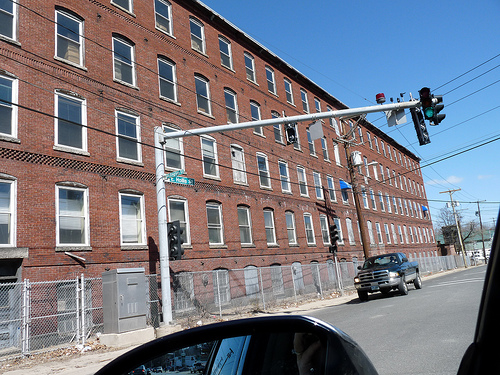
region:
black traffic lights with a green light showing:
[409, 87, 449, 145]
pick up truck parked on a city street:
[351, 252, 421, 299]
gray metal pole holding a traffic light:
[152, 124, 174, 334]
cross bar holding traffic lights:
[166, 98, 428, 145]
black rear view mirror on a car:
[98, 312, 380, 372]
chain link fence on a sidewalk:
[0, 252, 475, 362]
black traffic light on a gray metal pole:
[166, 220, 186, 265]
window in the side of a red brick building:
[0, 1, 432, 256]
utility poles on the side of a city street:
[439, 184, 492, 269]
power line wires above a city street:
[346, 53, 496, 188]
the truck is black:
[351, 239, 423, 289]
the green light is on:
[418, 105, 440, 125]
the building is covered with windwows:
[138, 90, 436, 250]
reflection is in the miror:
[173, 340, 321, 374]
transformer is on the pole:
[345, 148, 369, 173]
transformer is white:
[347, 151, 369, 164]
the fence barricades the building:
[245, 263, 341, 310]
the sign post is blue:
[161, 165, 198, 187]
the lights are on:
[343, 264, 402, 286]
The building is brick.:
[1, 0, 452, 367]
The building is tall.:
[0, 0, 455, 368]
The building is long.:
[1, 0, 447, 363]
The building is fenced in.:
[1, 0, 446, 372]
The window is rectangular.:
[51, 85, 94, 158]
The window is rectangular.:
[51, 178, 98, 257]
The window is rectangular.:
[49, 4, 86, 71]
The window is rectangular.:
[103, 27, 150, 99]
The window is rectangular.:
[108, 105, 148, 167]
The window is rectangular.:
[116, 182, 152, 260]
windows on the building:
[7, 50, 207, 145]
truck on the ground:
[336, 245, 431, 310]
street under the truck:
[406, 275, 453, 326]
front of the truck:
[350, 260, 397, 295]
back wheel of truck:
[405, 266, 430, 291]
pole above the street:
[237, 82, 387, 139]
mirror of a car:
[150, 310, 331, 370]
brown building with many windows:
[5, 27, 340, 282]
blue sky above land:
[315, 5, 426, 60]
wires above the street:
[435, 63, 492, 145]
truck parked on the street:
[343, 248, 428, 300]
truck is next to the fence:
[344, 249, 428, 300]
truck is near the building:
[332, 233, 429, 304]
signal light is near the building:
[142, 85, 462, 160]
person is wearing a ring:
[247, 306, 347, 371]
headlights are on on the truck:
[330, 246, 425, 301]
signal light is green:
[391, 75, 456, 155]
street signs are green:
[162, 167, 196, 189]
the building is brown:
[198, 139, 435, 254]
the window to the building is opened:
[283, 118, 302, 150]